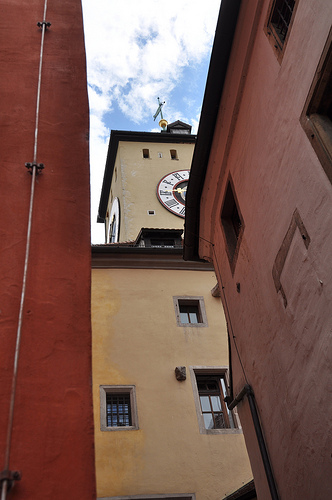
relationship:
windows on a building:
[97, 364, 234, 439] [94, 263, 229, 493]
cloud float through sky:
[82, 1, 233, 248] [83, 1, 222, 259]